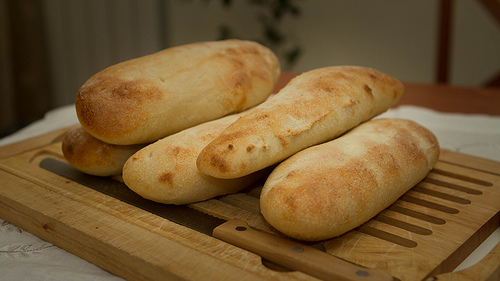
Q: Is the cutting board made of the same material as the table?
A: Yes, both the cutting board and the table are made of wood.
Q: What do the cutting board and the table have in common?
A: The material, both the cutting board and the table are wooden.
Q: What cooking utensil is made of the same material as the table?
A: The cutting board is made of the same material as the table.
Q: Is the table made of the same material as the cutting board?
A: Yes, both the table and the cutting board are made of wood.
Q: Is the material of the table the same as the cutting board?
A: Yes, both the table and the cutting board are made of wood.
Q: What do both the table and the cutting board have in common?
A: The material, both the table and the cutting board are wooden.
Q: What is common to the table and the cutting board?
A: The material, both the table and the cutting board are wooden.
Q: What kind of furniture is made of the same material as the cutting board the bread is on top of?
A: The table is made of the same material as the cutting board.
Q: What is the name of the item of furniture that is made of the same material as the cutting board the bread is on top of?
A: The piece of furniture is a table.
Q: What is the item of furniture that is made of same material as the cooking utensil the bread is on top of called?
A: The piece of furniture is a table.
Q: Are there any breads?
A: Yes, there is a bread.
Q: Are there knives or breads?
A: Yes, there is a bread.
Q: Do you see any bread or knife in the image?
A: Yes, there is a bread.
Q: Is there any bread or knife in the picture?
A: Yes, there is a bread.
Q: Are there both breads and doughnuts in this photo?
A: No, there is a bread but no donuts.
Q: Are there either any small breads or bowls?
A: Yes, there is a small bread.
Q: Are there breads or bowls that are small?
A: Yes, the bread is small.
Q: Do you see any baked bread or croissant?
A: Yes, there is a baked bread.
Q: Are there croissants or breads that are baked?
A: Yes, the bread is baked.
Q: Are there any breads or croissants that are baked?
A: Yes, the bread is baked.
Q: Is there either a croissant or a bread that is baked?
A: Yes, the bread is baked.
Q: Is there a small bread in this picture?
A: Yes, there is a small bread.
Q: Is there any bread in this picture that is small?
A: Yes, there is a bread that is small.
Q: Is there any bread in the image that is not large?
A: Yes, there is a small bread.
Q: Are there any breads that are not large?
A: Yes, there is a small bread.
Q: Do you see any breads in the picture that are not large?
A: Yes, there is a small bread.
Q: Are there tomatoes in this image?
A: No, there are no tomatoes.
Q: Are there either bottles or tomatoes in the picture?
A: No, there are no tomatoes or bottles.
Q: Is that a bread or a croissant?
A: That is a bread.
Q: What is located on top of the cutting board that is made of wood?
A: The bread is on top of the cutting board.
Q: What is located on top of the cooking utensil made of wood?
A: The bread is on top of the cutting board.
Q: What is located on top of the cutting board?
A: The bread is on top of the cutting board.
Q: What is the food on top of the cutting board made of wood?
A: The food is a bread.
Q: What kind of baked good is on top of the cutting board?
A: The food is a bread.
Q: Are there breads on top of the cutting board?
A: Yes, there is a bread on top of the cutting board.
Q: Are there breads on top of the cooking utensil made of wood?
A: Yes, there is a bread on top of the cutting board.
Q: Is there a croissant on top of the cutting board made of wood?
A: No, there is a bread on top of the cutting board.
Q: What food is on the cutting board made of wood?
A: The food is a bread.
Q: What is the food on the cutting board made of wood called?
A: The food is a bread.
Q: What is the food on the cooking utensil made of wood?
A: The food is a bread.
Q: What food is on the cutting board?
A: The food is a bread.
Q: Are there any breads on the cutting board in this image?
A: Yes, there is a bread on the cutting board.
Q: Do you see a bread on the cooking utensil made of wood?
A: Yes, there is a bread on the cutting board.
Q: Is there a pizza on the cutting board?
A: No, there is a bread on the cutting board.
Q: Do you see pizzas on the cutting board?
A: No, there is a bread on the cutting board.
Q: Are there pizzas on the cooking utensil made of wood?
A: No, there is a bread on the cutting board.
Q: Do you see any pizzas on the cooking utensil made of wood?
A: No, there is a bread on the cutting board.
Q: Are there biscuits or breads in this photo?
A: Yes, there is a bread.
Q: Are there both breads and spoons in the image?
A: No, there is a bread but no spoons.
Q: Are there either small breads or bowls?
A: Yes, there is a small bread.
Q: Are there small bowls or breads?
A: Yes, there is a small bread.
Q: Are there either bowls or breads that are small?
A: Yes, the bread is small.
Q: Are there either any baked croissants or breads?
A: Yes, there is a baked bread.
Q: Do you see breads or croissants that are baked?
A: Yes, the bread is baked.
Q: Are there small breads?
A: Yes, there is a small bread.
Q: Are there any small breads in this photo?
A: Yes, there is a small bread.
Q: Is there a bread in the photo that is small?
A: Yes, there is a bread that is small.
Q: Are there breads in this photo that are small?
A: Yes, there is a bread that is small.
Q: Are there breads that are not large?
A: Yes, there is a small bread.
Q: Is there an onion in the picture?
A: No, there are no onions.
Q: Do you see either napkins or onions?
A: No, there are no onions or napkins.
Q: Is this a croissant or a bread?
A: This is a bread.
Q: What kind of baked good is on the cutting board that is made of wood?
A: The food is a bread.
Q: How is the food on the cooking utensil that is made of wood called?
A: The food is a bread.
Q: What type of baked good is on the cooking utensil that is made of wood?
A: The food is a bread.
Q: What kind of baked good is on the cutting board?
A: The food is a bread.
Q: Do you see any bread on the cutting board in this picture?
A: Yes, there is a bread on the cutting board.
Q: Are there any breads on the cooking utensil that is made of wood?
A: Yes, there is a bread on the cutting board.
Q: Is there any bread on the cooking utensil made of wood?
A: Yes, there is a bread on the cutting board.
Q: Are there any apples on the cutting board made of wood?
A: No, there is a bread on the cutting board.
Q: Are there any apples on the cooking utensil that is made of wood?
A: No, there is a bread on the cutting board.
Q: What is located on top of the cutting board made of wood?
A: The bread is on top of the cutting board.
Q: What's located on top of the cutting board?
A: The bread is on top of the cutting board.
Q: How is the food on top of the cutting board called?
A: The food is a bread.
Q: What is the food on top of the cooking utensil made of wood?
A: The food is a bread.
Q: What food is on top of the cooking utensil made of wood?
A: The food is a bread.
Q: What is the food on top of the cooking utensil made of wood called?
A: The food is a bread.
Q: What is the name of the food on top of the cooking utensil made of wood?
A: The food is a bread.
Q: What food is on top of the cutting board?
A: The food is a bread.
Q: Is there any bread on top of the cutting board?
A: Yes, there is a bread on top of the cutting board.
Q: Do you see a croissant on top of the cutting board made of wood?
A: No, there is a bread on top of the cutting board.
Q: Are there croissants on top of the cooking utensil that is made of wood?
A: No, there is a bread on top of the cutting board.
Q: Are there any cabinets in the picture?
A: No, there are no cabinets.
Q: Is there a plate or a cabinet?
A: No, there are no cabinets or plates.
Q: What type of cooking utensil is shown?
A: The cooking utensil is a cutting board.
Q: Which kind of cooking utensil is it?
A: The cooking utensil is a cutting board.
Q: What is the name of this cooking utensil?
A: This is a cutting board.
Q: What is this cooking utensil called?
A: This is a cutting board.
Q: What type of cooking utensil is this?
A: This is a cutting board.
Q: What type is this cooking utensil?
A: This is a cutting board.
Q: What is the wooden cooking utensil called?
A: The cooking utensil is a cutting board.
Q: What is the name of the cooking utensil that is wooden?
A: The cooking utensil is a cutting board.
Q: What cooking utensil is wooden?
A: The cooking utensil is a cutting board.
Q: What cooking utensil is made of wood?
A: The cooking utensil is a cutting board.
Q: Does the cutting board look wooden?
A: Yes, the cutting board is wooden.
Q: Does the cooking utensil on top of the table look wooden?
A: Yes, the cutting board is wooden.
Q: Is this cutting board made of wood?
A: Yes, the cutting board is made of wood.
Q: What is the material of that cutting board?
A: The cutting board is made of wood.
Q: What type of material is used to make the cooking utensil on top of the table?
A: The cutting board is made of wood.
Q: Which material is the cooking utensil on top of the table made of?
A: The cutting board is made of wood.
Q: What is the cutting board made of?
A: The cutting board is made of wood.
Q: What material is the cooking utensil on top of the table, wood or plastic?
A: The cutting board is made of wood.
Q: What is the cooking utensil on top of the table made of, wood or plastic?
A: The cutting board is made of wood.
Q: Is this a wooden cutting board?
A: Yes, this is a wooden cutting board.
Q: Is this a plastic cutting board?
A: No, this is a wooden cutting board.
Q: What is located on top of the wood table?
A: The cutting board is on top of the table.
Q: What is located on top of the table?
A: The cutting board is on top of the table.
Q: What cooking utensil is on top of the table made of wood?
A: The cooking utensil is a cutting board.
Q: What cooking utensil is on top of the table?
A: The cooking utensil is a cutting board.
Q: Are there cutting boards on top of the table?
A: Yes, there is a cutting board on top of the table.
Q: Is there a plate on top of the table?
A: No, there is a cutting board on top of the table.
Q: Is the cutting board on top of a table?
A: Yes, the cutting board is on top of a table.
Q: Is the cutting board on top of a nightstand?
A: No, the cutting board is on top of a table.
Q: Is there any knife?
A: Yes, there is a knife.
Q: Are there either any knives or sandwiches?
A: Yes, there is a knife.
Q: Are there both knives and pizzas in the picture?
A: No, there is a knife but no pizzas.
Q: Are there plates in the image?
A: No, there are no plates.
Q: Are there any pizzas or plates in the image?
A: No, there are no plates or pizzas.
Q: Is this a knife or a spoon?
A: This is a knife.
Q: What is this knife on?
A: The knife is on the cutting board.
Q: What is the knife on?
A: The knife is on the cutting board.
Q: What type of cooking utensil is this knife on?
A: The knife is on the cutting board.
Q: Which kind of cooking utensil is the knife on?
A: The knife is on the cutting board.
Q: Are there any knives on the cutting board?
A: Yes, there is a knife on the cutting board.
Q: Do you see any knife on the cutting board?
A: Yes, there is a knife on the cutting board.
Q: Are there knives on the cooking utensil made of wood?
A: Yes, there is a knife on the cutting board.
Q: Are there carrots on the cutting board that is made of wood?
A: No, there is a knife on the cutting board.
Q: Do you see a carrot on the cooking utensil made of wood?
A: No, there is a knife on the cutting board.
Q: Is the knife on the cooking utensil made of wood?
A: Yes, the knife is on the cutting board.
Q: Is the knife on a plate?
A: No, the knife is on the cutting board.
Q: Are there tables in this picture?
A: Yes, there is a table.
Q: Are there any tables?
A: Yes, there is a table.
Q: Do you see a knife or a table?
A: Yes, there is a table.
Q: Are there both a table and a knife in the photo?
A: Yes, there are both a table and a knife.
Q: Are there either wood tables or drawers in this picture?
A: Yes, there is a wood table.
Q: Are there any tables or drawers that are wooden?
A: Yes, the table is wooden.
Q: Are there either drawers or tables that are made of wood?
A: Yes, the table is made of wood.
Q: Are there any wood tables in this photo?
A: Yes, there is a wood table.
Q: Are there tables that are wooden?
A: Yes, there is a table that is wooden.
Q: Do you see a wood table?
A: Yes, there is a table that is made of wood.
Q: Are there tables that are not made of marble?
A: Yes, there is a table that is made of wood.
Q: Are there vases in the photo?
A: No, there are no vases.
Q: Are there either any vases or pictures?
A: No, there are no vases or pictures.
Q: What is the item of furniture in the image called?
A: The piece of furniture is a table.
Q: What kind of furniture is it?
A: The piece of furniture is a table.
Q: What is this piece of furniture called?
A: That is a table.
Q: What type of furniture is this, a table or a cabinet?
A: That is a table.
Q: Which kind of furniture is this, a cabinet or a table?
A: That is a table.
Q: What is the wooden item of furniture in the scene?
A: The piece of furniture is a table.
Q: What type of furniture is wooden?
A: The furniture is a table.